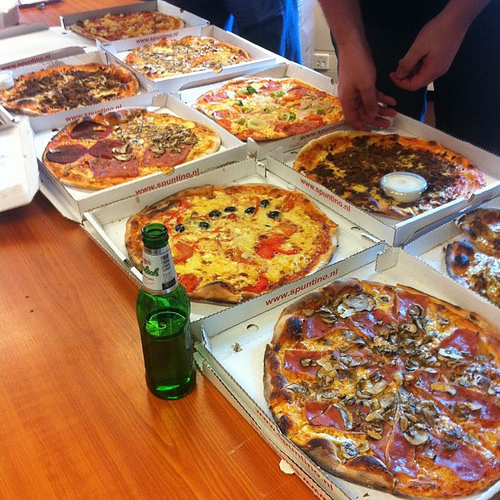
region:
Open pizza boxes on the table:
[0, 4, 499, 499]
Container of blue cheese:
[377, 167, 432, 207]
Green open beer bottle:
[132, 218, 199, 402]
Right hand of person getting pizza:
[315, 0, 400, 139]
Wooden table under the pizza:
[0, 2, 330, 498]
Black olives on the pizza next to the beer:
[167, 193, 288, 238]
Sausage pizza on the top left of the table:
[0, 57, 141, 117]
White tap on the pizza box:
[270, 452, 299, 481]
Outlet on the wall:
[309, 50, 334, 73]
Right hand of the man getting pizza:
[385, 0, 493, 95]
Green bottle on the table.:
[132, 220, 204, 398]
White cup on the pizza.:
[381, 170, 428, 202]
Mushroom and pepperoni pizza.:
[265, 276, 493, 493]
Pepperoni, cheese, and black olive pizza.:
[142, 183, 337, 305]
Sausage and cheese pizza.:
[292, 133, 484, 220]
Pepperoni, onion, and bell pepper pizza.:
[200, 70, 346, 140]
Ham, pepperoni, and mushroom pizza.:
[43, 110, 200, 185]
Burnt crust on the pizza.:
[443, 234, 474, 281]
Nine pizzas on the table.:
[0, 7, 495, 497]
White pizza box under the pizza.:
[186, 247, 497, 497]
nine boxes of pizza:
[26, 13, 498, 495]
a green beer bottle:
[138, 221, 204, 400]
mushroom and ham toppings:
[290, 296, 489, 496]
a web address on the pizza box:
[258, 252, 342, 313]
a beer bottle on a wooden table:
[3, 195, 336, 494]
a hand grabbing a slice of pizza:
[298, 2, 395, 131]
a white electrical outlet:
[310, 50, 331, 68]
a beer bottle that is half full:
[128, 220, 208, 402]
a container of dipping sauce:
[376, 171, 431, 208]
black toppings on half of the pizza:
[130, 196, 290, 231]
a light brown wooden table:
[0, 189, 321, 499]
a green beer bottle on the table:
[135, 223, 197, 400]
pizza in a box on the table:
[186, 246, 498, 498]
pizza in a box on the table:
[82, 155, 387, 337]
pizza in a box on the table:
[15, 93, 248, 220]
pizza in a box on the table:
[1, 48, 158, 130]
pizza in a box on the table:
[59, 0, 209, 54]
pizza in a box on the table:
[99, 23, 275, 94]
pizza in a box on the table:
[170, 62, 390, 160]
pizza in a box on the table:
[255, 108, 498, 245]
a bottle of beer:
[136, 227, 198, 395]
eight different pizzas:
[12, 16, 497, 479]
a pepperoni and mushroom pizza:
[263, 282, 498, 498]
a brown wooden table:
[5, 294, 133, 497]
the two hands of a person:
[332, 19, 464, 129]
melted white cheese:
[220, 224, 255, 255]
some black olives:
[198, 206, 277, 228]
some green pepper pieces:
[237, 87, 297, 119]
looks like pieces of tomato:
[255, 232, 281, 292]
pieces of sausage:
[26, 77, 103, 103]